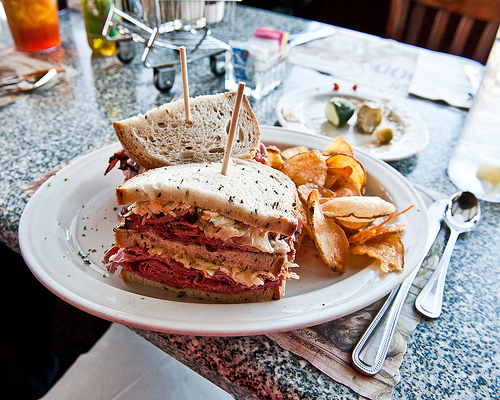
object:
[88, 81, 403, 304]
food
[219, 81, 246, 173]
peg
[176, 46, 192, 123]
peg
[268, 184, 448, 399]
placemat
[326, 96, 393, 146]
food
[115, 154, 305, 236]
bread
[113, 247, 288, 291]
bread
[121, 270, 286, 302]
bread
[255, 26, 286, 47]
sugar packets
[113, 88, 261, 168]
bread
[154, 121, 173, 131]
hole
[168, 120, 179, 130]
hole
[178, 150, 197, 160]
hole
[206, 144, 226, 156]
hole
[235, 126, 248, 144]
hole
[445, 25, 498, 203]
glass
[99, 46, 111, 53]
water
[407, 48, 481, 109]
napkin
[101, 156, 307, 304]
sandwich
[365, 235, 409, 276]
potato chips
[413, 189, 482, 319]
spoon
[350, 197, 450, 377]
butter knife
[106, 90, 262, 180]
sandwich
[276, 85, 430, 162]
plate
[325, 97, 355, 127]
vegetable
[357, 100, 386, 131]
vegetable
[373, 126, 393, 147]
vegetable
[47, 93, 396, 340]
plate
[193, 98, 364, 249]
vegetables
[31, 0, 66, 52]
drink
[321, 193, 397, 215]
chips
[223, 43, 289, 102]
caddy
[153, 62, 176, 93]
wheel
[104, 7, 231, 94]
cart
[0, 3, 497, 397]
table pattern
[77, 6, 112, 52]
tea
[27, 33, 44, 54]
glass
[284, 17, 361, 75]
placemat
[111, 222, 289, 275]
bread slice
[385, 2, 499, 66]
chair back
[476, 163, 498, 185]
lemon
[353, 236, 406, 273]
chips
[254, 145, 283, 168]
chips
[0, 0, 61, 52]
cup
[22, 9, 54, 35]
beverage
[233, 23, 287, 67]
packets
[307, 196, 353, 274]
chip